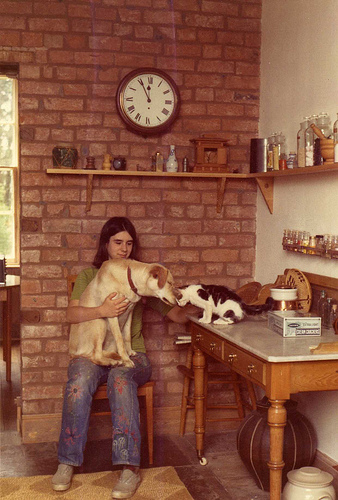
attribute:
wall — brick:
[0, 1, 260, 452]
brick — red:
[26, 15, 71, 40]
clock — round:
[106, 58, 188, 142]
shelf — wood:
[40, 152, 261, 227]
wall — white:
[250, 3, 336, 463]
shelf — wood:
[250, 148, 337, 222]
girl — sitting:
[50, 214, 158, 500]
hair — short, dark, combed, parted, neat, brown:
[86, 212, 141, 278]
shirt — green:
[58, 262, 179, 370]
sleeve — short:
[142, 295, 178, 321]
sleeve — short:
[65, 272, 93, 309]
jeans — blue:
[54, 347, 155, 475]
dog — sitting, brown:
[64, 251, 179, 375]